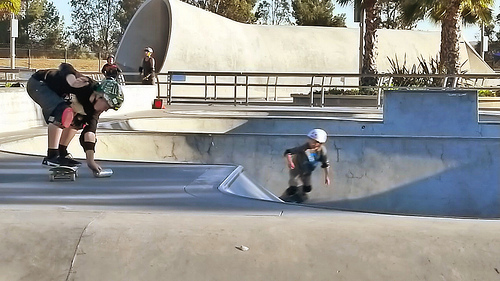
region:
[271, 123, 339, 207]
Small boy skating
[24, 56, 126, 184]
Skateboarder picking up soda can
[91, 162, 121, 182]
Soda can laying on ground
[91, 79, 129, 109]
Green helmet on boys head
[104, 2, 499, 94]
Tunnel shaped skate park building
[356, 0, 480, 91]
Palm trees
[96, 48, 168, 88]
Two boys walking in park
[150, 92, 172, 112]
Orange cone on its side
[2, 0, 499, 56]
Trees in background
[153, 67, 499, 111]
Metal railing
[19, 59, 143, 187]
Woman bending over to pick up can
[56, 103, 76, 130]
Pink knee pad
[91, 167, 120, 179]
Empty can on the ground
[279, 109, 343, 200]
Young person skateboarding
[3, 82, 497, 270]
Image of a skate park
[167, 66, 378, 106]
Gray metal fence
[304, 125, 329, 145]
White helmet on head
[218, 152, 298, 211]
Section of a gray skate ramp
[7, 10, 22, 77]
Tall wooden pole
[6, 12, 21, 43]
White sign attached to a pole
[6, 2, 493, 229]
Community provided skate park.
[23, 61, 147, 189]
Girl skater sets up aluminum can for a skating trick.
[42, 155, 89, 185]
Skateboard with four wheels sits idle.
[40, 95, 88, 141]
Knee pads for knee protection.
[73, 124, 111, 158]
Elbow pads for elbow protection.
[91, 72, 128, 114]
Helmet for head protection.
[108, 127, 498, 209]
Half pipe area of skate park.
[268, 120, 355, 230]
Boy skater inside the half pipe.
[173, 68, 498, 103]
Safety railing to support skaters and protect onlookers.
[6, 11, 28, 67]
Sign with liability disclaimer on it.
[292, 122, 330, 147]
white helmet on skate boarder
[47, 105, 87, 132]
pink and black kneepads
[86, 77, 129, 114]
green helmet of skateboarder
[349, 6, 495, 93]
trees in skateboard park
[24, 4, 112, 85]
trees in the background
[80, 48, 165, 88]
people walking near skateboard park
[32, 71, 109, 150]
black shirt of skateboarder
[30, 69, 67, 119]
grey shorts of skateboarder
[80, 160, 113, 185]
grey soda can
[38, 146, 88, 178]
black socks of skateboarder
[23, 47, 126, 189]
a young skateboarder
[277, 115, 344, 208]
a teenager riding a skateboard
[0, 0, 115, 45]
a bunch of trees in the afternoon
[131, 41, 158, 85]
a teenager watching the others skateboard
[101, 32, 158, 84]
two skateboarders hanging out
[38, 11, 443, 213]
a big skatepark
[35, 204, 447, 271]
the cement ground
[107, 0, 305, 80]
a skateboarding tunnel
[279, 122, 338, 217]
a kid wearing a white helmet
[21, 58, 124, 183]
a teenager picking up a can